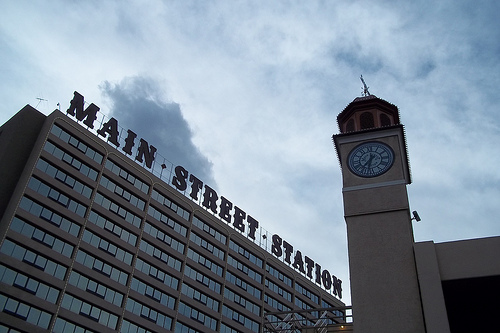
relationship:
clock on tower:
[345, 141, 396, 179] [330, 71, 427, 332]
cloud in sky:
[121, 0, 348, 281] [0, 0, 500, 323]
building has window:
[0, 101, 345, 332] [50, 122, 63, 137]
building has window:
[0, 101, 345, 332] [44, 138, 55, 155]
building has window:
[0, 101, 345, 332] [34, 157, 50, 173]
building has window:
[0, 101, 345, 332] [26, 173, 41, 191]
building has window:
[0, 101, 345, 332] [19, 194, 33, 212]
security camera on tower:
[411, 210, 422, 222] [330, 71, 427, 332]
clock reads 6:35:
[345, 141, 396, 179] [359, 152, 379, 173]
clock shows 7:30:
[345, 141, 396, 179] [359, 152, 379, 173]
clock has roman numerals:
[345, 141, 396, 179] [365, 144, 374, 154]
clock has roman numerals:
[345, 141, 396, 179] [374, 143, 381, 153]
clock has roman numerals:
[345, 141, 396, 179] [379, 148, 386, 156]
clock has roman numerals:
[345, 141, 396, 179] [380, 154, 391, 160]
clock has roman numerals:
[345, 141, 396, 179] [379, 160, 389, 167]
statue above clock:
[356, 75, 371, 98] [345, 141, 396, 179]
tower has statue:
[330, 71, 427, 332] [356, 75, 371, 98]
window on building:
[50, 122, 63, 137] [0, 101, 345, 332]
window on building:
[44, 138, 55, 155] [0, 101, 345, 332]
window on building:
[34, 157, 50, 173] [0, 101, 345, 332]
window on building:
[26, 173, 41, 191] [0, 101, 345, 332]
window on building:
[19, 194, 33, 212] [0, 101, 345, 332]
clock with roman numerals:
[345, 141, 396, 179] [365, 144, 374, 154]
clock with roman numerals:
[345, 141, 396, 179] [374, 143, 381, 153]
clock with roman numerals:
[345, 141, 396, 179] [379, 148, 386, 156]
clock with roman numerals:
[345, 141, 396, 179] [380, 154, 391, 160]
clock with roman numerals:
[345, 141, 396, 179] [379, 160, 389, 167]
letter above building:
[67, 89, 100, 130] [0, 101, 345, 332]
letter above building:
[96, 114, 121, 148] [0, 101, 345, 332]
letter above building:
[123, 128, 139, 158] [0, 101, 345, 332]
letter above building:
[135, 135, 158, 170] [0, 101, 345, 332]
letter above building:
[170, 165, 189, 191] [0, 101, 345, 332]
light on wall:
[338, 323, 345, 332] [326, 323, 353, 332]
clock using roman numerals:
[345, 141, 396, 179] [365, 144, 374, 154]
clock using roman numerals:
[345, 141, 396, 179] [374, 143, 381, 153]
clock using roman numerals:
[345, 141, 396, 179] [379, 148, 386, 156]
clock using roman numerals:
[345, 141, 396, 179] [380, 154, 391, 160]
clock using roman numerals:
[345, 141, 396, 179] [379, 160, 389, 167]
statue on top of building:
[300, 59, 420, 128] [336, 97, 484, 325]